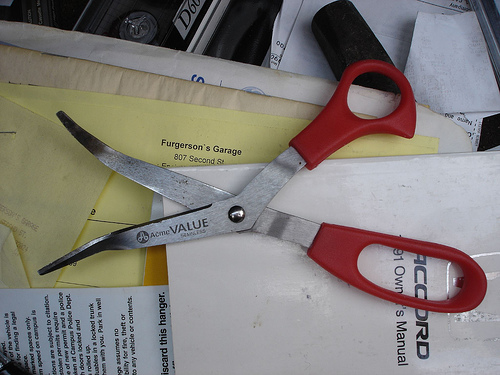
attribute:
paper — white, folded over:
[401, 5, 498, 121]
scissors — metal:
[27, 77, 488, 320]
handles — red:
[290, 60, 487, 312]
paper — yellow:
[17, 90, 261, 200]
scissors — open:
[23, 58, 463, 342]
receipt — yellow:
[0, 81, 437, 289]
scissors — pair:
[9, 49, 496, 360]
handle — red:
[305, 219, 488, 313]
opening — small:
[342, 222, 476, 317]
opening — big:
[321, 47, 421, 147]